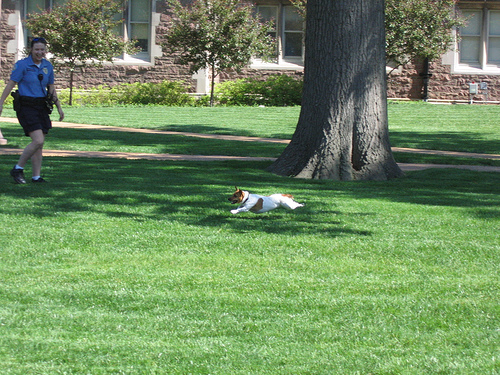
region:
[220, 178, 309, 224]
a dog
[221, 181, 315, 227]
a brown and white dog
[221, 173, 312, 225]
a dog laying in the grass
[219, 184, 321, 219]
a brown and white dog laying in the grass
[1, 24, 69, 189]
a woman in uniform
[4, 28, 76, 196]
a woman in a uniform walks toward the dog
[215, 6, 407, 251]
the dog is near a large tree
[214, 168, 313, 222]
the dog is wearing a collar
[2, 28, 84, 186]
the woman is wearing shorts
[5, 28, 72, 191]
the woman has a microphone on her shirt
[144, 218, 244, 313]
the grass is green and visible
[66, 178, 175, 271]
the grass is green and visible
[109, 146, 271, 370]
the grass is green and visible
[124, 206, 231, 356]
the grass is green and visible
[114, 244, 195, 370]
the grass is green and visible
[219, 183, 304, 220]
a white and brown dog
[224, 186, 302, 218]
a running dog on grass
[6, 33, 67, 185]
a woman standing on grass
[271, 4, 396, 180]
a large grey tree trunk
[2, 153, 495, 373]
a green grass yard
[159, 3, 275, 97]
a small green tree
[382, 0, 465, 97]
a small green tree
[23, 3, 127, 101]
a small green tree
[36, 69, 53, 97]
a two way radio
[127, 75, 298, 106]
a line of small green bushes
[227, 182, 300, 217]
the small dog in mid air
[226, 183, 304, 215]
the brown and white dog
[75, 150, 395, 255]
the shadow from the tree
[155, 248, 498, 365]
the lush green grass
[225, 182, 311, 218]
the brown and white dog jumping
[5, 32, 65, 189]
the woman smiling at the dog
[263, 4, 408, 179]
the big brown tree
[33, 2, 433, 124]
the small trees near the building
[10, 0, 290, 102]
the building in the back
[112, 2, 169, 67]
the window on the building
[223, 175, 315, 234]
dog running in lawn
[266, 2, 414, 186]
trunk of a tree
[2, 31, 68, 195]
female in the grass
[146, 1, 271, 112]
green tree by building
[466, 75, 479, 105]
utility box by building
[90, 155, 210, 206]
shadows casted on the ground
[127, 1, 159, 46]
window of a building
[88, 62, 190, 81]
brick facade of a building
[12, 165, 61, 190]
sneakers on a female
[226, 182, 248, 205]
face of a dog